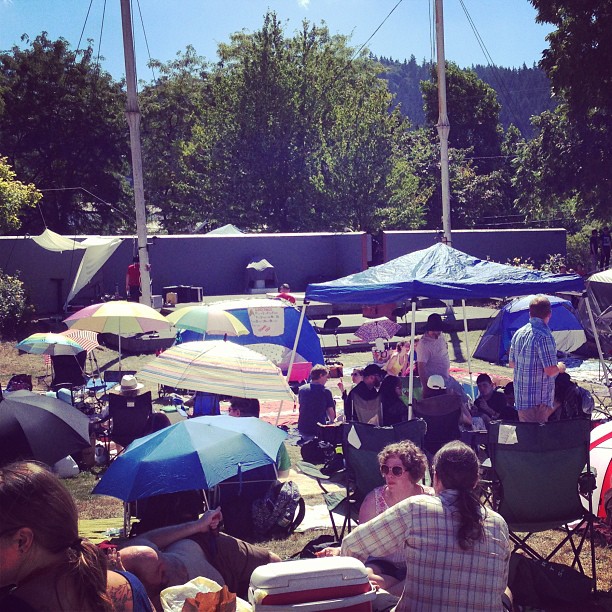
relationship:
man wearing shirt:
[509, 295, 566, 422] [508, 320, 559, 409]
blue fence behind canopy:
[0, 227, 567, 315] [284, 243, 604, 418]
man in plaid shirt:
[326, 421, 524, 610] [337, 484, 510, 597]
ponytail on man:
[457, 478, 490, 549] [344, 425, 513, 597]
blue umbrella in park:
[90, 390, 302, 505] [11, 234, 596, 595]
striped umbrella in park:
[143, 323, 309, 426] [11, 234, 596, 595]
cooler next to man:
[226, 553, 384, 610] [344, 427, 506, 609]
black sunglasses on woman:
[377, 464, 410, 481] [356, 427, 446, 497]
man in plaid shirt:
[503, 290, 574, 446] [510, 318, 566, 401]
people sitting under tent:
[277, 230, 596, 471] [303, 207, 604, 323]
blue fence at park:
[7, 231, 587, 326] [11, 234, 596, 595]